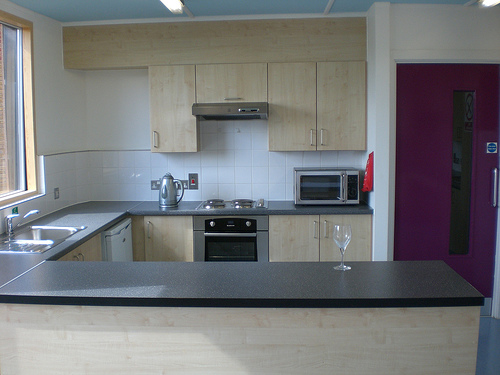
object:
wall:
[31, 54, 150, 156]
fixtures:
[6, 207, 40, 235]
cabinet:
[267, 62, 366, 152]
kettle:
[159, 173, 184, 208]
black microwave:
[293, 167, 359, 204]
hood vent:
[192, 102, 268, 120]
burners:
[205, 199, 253, 209]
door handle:
[493, 169, 498, 207]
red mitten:
[362, 151, 374, 192]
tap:
[7, 209, 40, 236]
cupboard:
[149, 63, 267, 152]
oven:
[193, 216, 270, 262]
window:
[0, 23, 24, 196]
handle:
[314, 221, 316, 237]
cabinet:
[269, 215, 371, 263]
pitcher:
[159, 172, 184, 208]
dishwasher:
[101, 217, 134, 261]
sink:
[0, 226, 84, 243]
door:
[392, 63, 499, 316]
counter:
[0, 200, 485, 375]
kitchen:
[0, 0, 500, 375]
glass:
[333, 223, 352, 270]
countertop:
[0, 199, 483, 307]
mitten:
[361, 152, 374, 192]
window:
[448, 90, 474, 255]